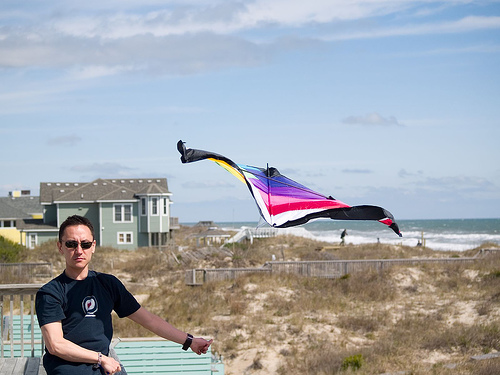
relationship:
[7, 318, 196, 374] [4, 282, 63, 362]
deck has railing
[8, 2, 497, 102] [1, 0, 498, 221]
clouds in sky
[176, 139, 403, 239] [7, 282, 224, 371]
kite flying from deck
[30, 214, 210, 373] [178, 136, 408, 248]
man flying kite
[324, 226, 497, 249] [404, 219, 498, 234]
waves in ocean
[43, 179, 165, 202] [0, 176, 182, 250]
shingled roof on beachfront home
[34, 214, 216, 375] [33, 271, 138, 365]
man wearing shirt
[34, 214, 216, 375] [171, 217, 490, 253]
man near beach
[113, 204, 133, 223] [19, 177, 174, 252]
window in building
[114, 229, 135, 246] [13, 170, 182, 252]
windows in building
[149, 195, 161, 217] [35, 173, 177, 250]
window in building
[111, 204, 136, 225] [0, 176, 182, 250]
window in beachfront home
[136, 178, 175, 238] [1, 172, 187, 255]
nose of a building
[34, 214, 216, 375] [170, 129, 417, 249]
man holding kite